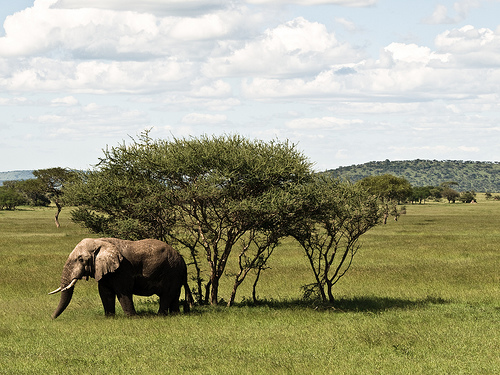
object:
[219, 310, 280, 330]
grass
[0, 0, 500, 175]
sky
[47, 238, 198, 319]
elephant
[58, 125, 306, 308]
tree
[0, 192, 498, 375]
wild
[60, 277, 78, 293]
tusk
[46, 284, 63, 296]
tusk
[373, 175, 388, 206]
tree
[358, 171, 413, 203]
tree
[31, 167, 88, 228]
tree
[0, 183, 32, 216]
tree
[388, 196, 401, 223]
tree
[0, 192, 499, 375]
field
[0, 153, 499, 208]
distance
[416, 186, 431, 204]
tree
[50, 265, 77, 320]
nose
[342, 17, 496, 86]
clouds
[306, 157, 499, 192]
hill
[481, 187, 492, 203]
tree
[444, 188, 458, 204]
tree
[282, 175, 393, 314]
tree